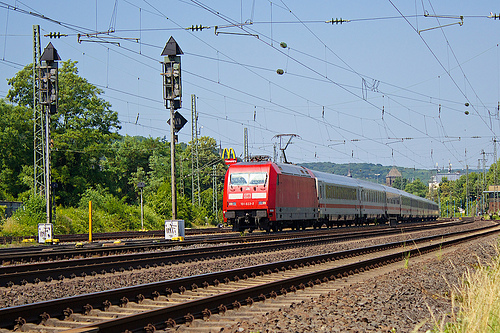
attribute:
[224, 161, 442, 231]
train — red, long, gray, silver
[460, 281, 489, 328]
grass — yellow, long, dry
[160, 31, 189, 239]
pole — metal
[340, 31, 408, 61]
sky — blue, clear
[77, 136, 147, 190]
trees — green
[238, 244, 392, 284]
tracks — metal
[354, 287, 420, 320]
gravel — gray, brown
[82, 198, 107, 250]
pole — yellow, short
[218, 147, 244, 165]
sign — yellow, red, white, giant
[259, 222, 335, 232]
wheels — black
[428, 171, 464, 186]
roof — blue